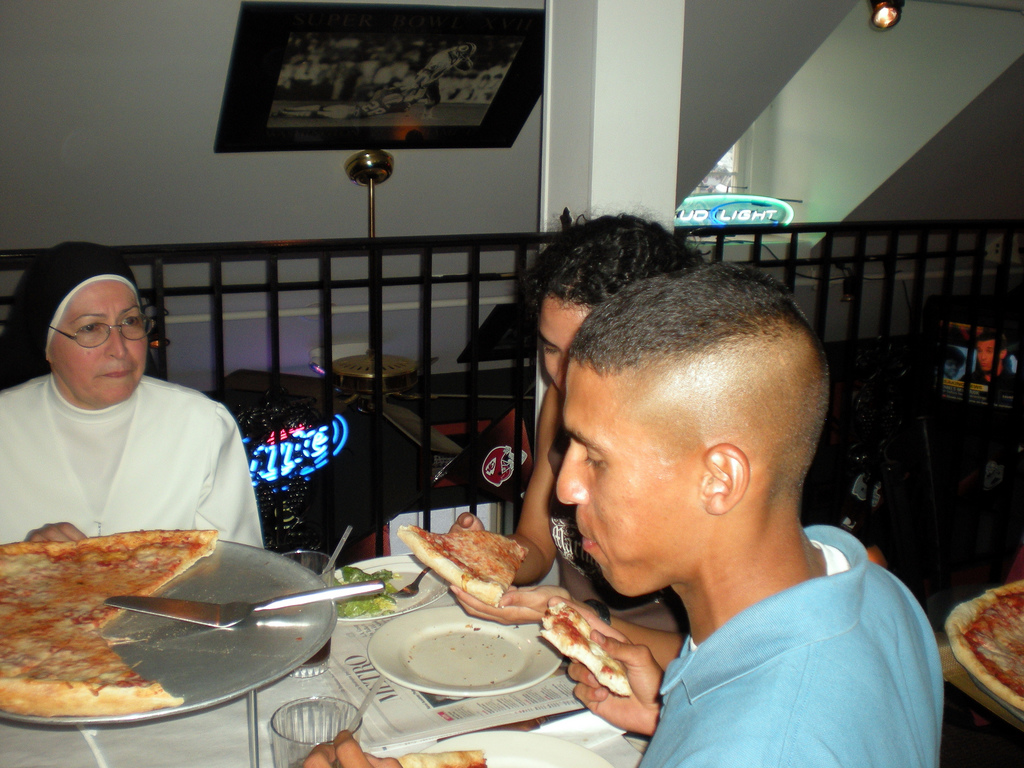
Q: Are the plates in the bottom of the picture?
A: Yes, the plates are in the bottom of the image.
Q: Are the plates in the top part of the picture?
A: No, the plates are in the bottom of the image.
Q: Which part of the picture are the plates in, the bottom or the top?
A: The plates are in the bottom of the image.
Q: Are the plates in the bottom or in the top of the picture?
A: The plates are in the bottom of the image.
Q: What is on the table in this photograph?
A: The plates are on the table.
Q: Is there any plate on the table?
A: Yes, there are plates on the table.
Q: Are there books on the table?
A: No, there are plates on the table.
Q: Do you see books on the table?
A: No, there are plates on the table.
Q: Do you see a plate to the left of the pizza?
A: Yes, there are plates to the left of the pizza.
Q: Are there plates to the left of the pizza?
A: Yes, there are plates to the left of the pizza.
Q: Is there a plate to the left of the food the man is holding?
A: Yes, there are plates to the left of the pizza.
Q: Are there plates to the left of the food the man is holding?
A: Yes, there are plates to the left of the pizza.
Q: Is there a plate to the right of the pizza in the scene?
A: No, the plates are to the left of the pizza.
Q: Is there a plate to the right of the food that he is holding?
A: No, the plates are to the left of the pizza.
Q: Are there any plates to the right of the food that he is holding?
A: No, the plates are to the left of the pizza.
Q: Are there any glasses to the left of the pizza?
A: No, there are plates to the left of the pizza.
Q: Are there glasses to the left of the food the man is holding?
A: No, there are plates to the left of the pizza.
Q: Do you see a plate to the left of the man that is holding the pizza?
A: Yes, there are plates to the left of the man.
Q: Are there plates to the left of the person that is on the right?
A: Yes, there are plates to the left of the man.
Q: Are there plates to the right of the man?
A: No, the plates are to the left of the man.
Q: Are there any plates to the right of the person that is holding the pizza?
A: No, the plates are to the left of the man.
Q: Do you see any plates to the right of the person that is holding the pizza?
A: No, the plates are to the left of the man.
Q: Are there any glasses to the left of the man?
A: No, there are plates to the left of the man.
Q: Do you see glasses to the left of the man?
A: No, there are plates to the left of the man.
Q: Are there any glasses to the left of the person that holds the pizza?
A: No, there are plates to the left of the man.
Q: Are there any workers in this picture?
A: No, there are no workers.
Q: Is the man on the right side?
A: Yes, the man is on the right of the image.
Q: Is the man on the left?
A: No, the man is on the right of the image.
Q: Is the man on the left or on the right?
A: The man is on the right of the image.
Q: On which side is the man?
A: The man is on the right of the image.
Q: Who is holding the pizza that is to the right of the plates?
A: The man is holding the pizza.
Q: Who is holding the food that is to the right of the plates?
A: The man is holding the pizza.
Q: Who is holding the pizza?
A: The man is holding the pizza.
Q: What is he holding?
A: The man is holding the pizza.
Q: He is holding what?
A: The man is holding the pizza.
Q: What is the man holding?
A: The man is holding the pizza.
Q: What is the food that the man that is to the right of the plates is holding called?
A: The food is a pizza.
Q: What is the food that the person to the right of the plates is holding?
A: The food is a pizza.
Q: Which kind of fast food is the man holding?
A: The man is holding the pizza.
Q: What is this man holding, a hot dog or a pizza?
A: The man is holding a pizza.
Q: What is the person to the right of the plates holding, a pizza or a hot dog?
A: The man is holding a pizza.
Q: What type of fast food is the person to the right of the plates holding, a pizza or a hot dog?
A: The man is holding a pizza.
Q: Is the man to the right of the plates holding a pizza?
A: Yes, the man is holding a pizza.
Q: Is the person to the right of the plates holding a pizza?
A: Yes, the man is holding a pizza.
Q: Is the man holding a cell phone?
A: No, the man is holding a pizza.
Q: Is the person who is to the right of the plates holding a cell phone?
A: No, the man is holding a pizza.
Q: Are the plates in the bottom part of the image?
A: Yes, the plates are in the bottom of the image.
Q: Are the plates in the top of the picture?
A: No, the plates are in the bottom of the image.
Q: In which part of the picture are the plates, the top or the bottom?
A: The plates are in the bottom of the image.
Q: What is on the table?
A: The plates are on the table.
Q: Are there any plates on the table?
A: Yes, there are plates on the table.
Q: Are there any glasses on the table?
A: No, there are plates on the table.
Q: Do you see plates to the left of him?
A: Yes, there are plates to the left of the man.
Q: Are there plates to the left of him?
A: Yes, there are plates to the left of the man.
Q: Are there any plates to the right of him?
A: No, the plates are to the left of the man.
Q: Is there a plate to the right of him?
A: No, the plates are to the left of the man.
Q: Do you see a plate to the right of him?
A: No, the plates are to the left of the man.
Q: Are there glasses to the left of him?
A: No, there are plates to the left of the man.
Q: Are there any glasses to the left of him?
A: No, there are plates to the left of the man.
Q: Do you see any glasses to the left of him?
A: No, there are plates to the left of the man.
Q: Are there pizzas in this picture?
A: Yes, there is a pizza.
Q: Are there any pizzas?
A: Yes, there is a pizza.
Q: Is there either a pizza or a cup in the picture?
A: Yes, there is a pizza.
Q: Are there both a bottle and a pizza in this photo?
A: No, there is a pizza but no bottles.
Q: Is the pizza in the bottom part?
A: Yes, the pizza is in the bottom of the image.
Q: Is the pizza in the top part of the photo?
A: No, the pizza is in the bottom of the image.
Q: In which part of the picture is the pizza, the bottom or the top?
A: The pizza is in the bottom of the image.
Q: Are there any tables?
A: Yes, there is a table.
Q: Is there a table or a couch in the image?
A: Yes, there is a table.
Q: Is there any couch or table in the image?
A: Yes, there is a table.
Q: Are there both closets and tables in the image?
A: No, there is a table but no closets.